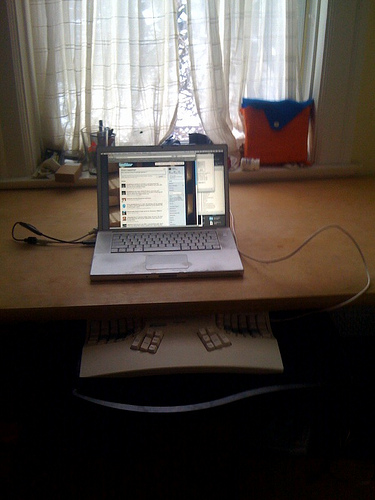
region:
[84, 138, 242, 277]
black and silver open laptop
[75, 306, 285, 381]
ergonomically correct computer keyboard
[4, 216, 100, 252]
black usb connector cable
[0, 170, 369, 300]
clean brown long desktop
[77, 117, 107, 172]
empty clear drinking glass on sill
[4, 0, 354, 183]
window with closed white sheer curtains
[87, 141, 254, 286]
Laptop sitting on a desk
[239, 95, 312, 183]
Red and blue pack sitting on window ledge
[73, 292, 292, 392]
Specialized keyboard on tray under desk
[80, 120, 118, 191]
glass of pens and pencils sitting on window sill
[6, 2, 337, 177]
Sheer curtains hanging on the window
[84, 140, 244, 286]
Open laptop turned on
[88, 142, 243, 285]
Laptop on with several windows open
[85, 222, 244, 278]
Laptop keyboard and mousepad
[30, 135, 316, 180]
Clutter and miscellaneous items on window sill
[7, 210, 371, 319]
Cables and keyboard connections attached to laptop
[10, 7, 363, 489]
Photo taken during the day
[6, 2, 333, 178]
Sunlight coming through the window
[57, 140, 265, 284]
The laptop is on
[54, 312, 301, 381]
Ergonomic computer keyboard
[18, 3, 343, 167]
The curtains are closed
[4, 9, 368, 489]
No people in the photo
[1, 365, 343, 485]
A chair in front of the desk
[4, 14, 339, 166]
White curtains with stripes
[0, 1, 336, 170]
A window on the wall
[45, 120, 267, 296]
this is a laptop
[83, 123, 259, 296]
the laptop is on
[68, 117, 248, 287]
the laptop is silver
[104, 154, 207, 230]
twitter is on the computer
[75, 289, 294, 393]
this is a keyboard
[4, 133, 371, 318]
computer sitting on a desk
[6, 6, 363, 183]
window in the background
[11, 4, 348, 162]
curtains on the window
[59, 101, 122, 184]
a cup of pens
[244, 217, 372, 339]
a white plugged chord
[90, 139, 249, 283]
laptop on top of desk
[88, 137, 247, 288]
laptop is dark silver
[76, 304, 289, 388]
keyboard under the desk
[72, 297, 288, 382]
odd shaped keyboard under table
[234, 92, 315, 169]
bag placed in front of window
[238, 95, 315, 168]
bag is orange and blue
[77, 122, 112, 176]
glass in window sill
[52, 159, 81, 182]
small block in window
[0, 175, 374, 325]
table is light brown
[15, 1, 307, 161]
curtain hanging in window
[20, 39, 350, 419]
a computer desk in front of window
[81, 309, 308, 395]
a curved computer keyboard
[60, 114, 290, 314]
a grey laptop opened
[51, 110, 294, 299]
an opened grey laptop